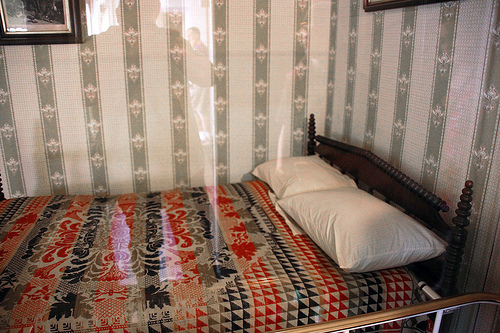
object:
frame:
[0, 0, 83, 46]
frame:
[362, 0, 446, 13]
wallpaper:
[0, 0, 331, 201]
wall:
[0, 0, 331, 199]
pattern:
[0, 190, 275, 323]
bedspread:
[0, 180, 434, 333]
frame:
[264, 291, 500, 333]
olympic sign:
[301, 111, 478, 295]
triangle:
[327, 284, 338, 291]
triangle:
[359, 288, 370, 297]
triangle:
[299, 308, 309, 317]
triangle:
[298, 270, 310, 275]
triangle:
[387, 282, 396, 292]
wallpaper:
[317, 0, 500, 333]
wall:
[308, 0, 500, 333]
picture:
[0, 0, 83, 47]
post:
[306, 113, 316, 156]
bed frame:
[306, 113, 473, 333]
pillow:
[277, 186, 446, 273]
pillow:
[251, 155, 358, 200]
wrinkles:
[287, 199, 442, 272]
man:
[187, 26, 214, 147]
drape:
[0, 0, 500, 333]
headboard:
[313, 134, 452, 288]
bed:
[0, 113, 474, 332]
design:
[0, 0, 500, 333]